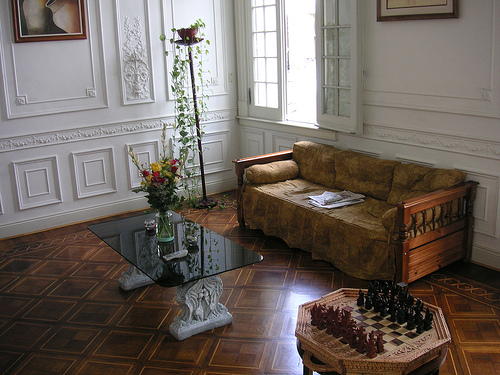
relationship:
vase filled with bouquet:
[156, 205, 176, 241] [123, 140, 187, 241]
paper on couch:
[310, 187, 367, 212] [232, 140, 472, 287]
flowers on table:
[130, 154, 182, 214] [87, 209, 264, 343]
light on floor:
[273, 281, 325, 373] [2, 189, 497, 372]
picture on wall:
[7, 1, 89, 45] [0, 2, 240, 219]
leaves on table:
[171, 82, 195, 150] [77, 204, 272, 339]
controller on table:
[158, 245, 195, 265] [77, 204, 272, 339]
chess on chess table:
[309, 300, 319, 324] [293, 280, 450, 374]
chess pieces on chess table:
[302, 299, 394, 357] [293, 280, 450, 374]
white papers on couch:
[306, 167, 370, 217] [232, 140, 472, 287]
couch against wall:
[232, 140, 472, 287] [338, 5, 498, 269]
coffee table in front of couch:
[84, 210, 264, 340] [232, 140, 472, 287]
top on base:
[83, 209, 264, 289] [117, 263, 233, 341]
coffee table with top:
[84, 210, 264, 340] [83, 209, 264, 289]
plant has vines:
[159, 15, 213, 210] [158, 11, 213, 211]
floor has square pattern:
[2, 189, 497, 375] [232, 287, 282, 308]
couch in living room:
[232, 140, 480, 284] [1, 1, 496, 371]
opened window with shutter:
[281, 0, 319, 128] [234, 1, 291, 127]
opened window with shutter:
[281, 0, 319, 128] [314, 0, 367, 137]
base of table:
[117, 263, 233, 341] [86, 189, 270, 344]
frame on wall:
[5, 8, 111, 63] [1, 4, 221, 209]